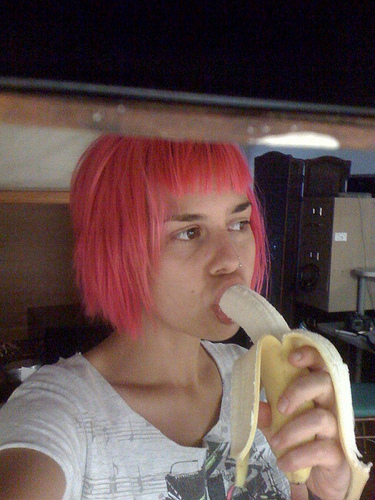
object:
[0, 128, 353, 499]
person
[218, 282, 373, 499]
banana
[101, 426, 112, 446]
music note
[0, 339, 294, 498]
shirt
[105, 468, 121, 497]
music note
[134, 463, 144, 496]
music note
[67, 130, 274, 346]
hair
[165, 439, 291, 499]
design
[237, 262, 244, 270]
stud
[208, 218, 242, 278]
nose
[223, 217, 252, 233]
eye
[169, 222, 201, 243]
eye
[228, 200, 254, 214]
eyebrow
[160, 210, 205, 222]
eyebrow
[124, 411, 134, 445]
music note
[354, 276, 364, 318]
pole